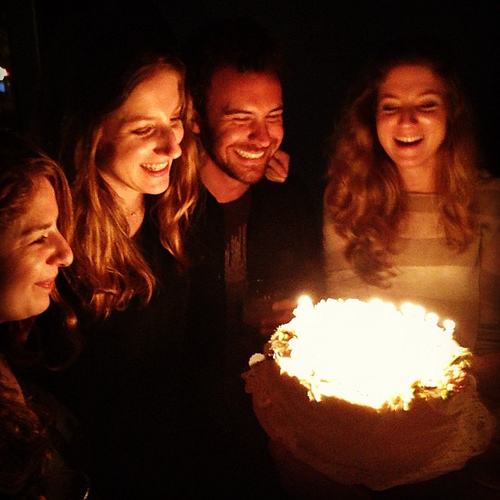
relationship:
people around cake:
[46, 71, 463, 336] [245, 277, 477, 467]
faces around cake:
[48, 68, 462, 254] [280, 291, 470, 453]